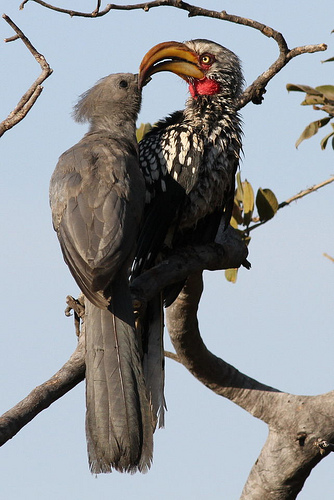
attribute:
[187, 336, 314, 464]
branch — bare, holding, grey, sticks, empty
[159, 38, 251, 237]
bird — black, large, beautiful, colorful, red, yellow, grey, close, sitting, small, looking, parent, loving, baby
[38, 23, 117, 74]
sky — blue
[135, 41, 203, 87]
beak — crooked, orange